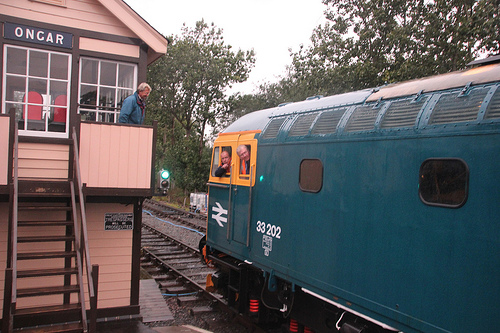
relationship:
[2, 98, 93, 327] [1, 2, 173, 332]
entrance to house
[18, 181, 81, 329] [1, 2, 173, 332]
steps to enter house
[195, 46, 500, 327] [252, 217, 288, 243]
train has a number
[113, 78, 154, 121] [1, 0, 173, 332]
person standing in house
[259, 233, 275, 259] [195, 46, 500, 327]
symbol on train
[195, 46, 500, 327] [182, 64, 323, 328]
train seen last part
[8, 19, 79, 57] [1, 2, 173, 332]
sign on building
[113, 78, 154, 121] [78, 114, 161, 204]
man standing on balcony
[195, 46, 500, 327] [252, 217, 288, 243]
train says on side 33 202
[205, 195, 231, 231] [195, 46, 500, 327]
logo on side of train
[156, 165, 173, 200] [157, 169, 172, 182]
traffic light lit to green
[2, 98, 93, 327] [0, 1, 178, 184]
stairs leading to second floor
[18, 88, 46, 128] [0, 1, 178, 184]
chair on second floor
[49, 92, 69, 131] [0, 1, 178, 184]
chair on second floor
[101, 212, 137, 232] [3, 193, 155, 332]
sign on first floor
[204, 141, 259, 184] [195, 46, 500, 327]
people looking out train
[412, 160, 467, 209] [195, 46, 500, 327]
window on side train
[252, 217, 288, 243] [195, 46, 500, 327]
numbers on side train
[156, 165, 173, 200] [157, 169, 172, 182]
traffic light in green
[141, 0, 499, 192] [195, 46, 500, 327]
trees ahead train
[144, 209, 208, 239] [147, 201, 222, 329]
blue chord near tracks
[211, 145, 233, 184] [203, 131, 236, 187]
conductor in window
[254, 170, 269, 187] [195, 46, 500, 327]
green light reflected on train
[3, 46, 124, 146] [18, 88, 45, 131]
waiting area has chair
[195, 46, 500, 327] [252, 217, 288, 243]
train labeled 33202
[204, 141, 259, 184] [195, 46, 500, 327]
men looking out train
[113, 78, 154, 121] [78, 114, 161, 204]
man standing on platform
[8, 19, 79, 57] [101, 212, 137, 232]
sign on platform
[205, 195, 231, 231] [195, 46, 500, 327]
arrows on train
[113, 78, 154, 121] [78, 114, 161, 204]
person stands on balcony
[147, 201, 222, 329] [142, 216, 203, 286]
track sort of rusty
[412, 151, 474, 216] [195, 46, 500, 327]
window on side train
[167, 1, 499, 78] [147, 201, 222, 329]
trees around track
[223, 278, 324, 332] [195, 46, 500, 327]
shocks under train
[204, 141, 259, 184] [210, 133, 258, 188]
men looking out train windows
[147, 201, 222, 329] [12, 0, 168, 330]
tracks beside train stop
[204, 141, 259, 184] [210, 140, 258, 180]
people looking out window